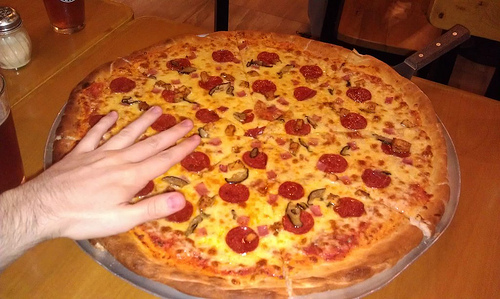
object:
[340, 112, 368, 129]
pepperoni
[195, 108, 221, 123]
pepperoni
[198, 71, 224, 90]
pepperoni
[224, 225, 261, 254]
pepperoni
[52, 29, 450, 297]
pizza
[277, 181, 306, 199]
pepperoni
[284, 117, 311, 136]
pepperoni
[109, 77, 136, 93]
pepperoni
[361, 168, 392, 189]
pepperoni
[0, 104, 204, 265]
arm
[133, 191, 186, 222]
finger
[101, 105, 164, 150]
ring finger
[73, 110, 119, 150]
pinky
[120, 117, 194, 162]
middle finger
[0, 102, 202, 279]
man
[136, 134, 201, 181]
index finger